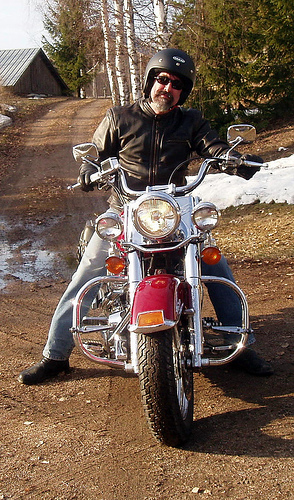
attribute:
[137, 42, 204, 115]
helmet — black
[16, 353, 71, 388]
boot — black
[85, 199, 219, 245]
headlights — white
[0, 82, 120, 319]
road — tan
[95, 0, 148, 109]
trunks — white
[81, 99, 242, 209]
jacket — black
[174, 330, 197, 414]
rims — silver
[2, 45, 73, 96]
barn — large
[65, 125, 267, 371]
frame — silver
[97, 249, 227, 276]
lights — orange